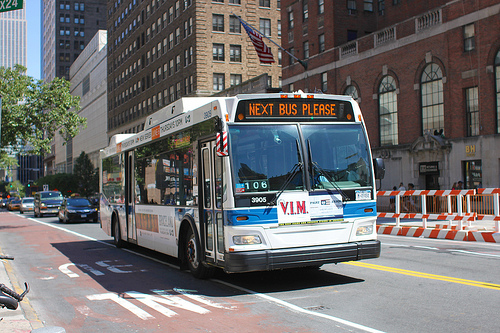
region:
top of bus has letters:
[243, 97, 343, 120]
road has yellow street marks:
[394, 252, 496, 316]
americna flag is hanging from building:
[217, 13, 334, 70]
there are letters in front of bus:
[267, 201, 328, 222]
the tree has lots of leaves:
[4, 68, 71, 189]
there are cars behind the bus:
[7, 175, 102, 220]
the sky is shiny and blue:
[9, 0, 61, 77]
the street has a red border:
[379, 181, 497, 254]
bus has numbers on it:
[236, 175, 276, 212]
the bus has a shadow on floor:
[47, 232, 348, 298]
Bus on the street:
[97, 93, 379, 278]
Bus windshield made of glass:
[225, 117, 372, 194]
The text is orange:
[247, 100, 336, 116]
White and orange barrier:
[377, 189, 497, 242]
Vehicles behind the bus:
[7, 189, 97, 219]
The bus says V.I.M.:
[280, 199, 307, 216]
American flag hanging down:
[235, 14, 276, 65]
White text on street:
[33, 259, 227, 319]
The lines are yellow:
[342, 260, 498, 291]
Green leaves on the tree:
[3, 65, 83, 158]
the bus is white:
[73, 91, 418, 283]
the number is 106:
[231, 170, 282, 204]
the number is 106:
[233, 167, 308, 214]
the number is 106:
[223, 156, 284, 196]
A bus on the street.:
[67, 112, 407, 297]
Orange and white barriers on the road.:
[386, 182, 472, 253]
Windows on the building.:
[123, 19, 228, 83]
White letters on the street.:
[58, 238, 176, 320]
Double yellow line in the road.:
[391, 262, 485, 305]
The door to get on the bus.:
[183, 128, 232, 250]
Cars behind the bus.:
[26, 186, 97, 226]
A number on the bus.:
[235, 164, 279, 202]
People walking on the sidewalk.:
[385, 169, 451, 214]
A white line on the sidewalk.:
[237, 286, 330, 331]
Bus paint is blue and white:
[97, 95, 380, 275]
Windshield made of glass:
[223, 120, 371, 191]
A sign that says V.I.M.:
[277, 199, 308, 217]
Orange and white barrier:
[377, 189, 499, 241]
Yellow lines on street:
[340, 259, 498, 287]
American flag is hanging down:
[231, 13, 273, 63]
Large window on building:
[415, 53, 444, 135]